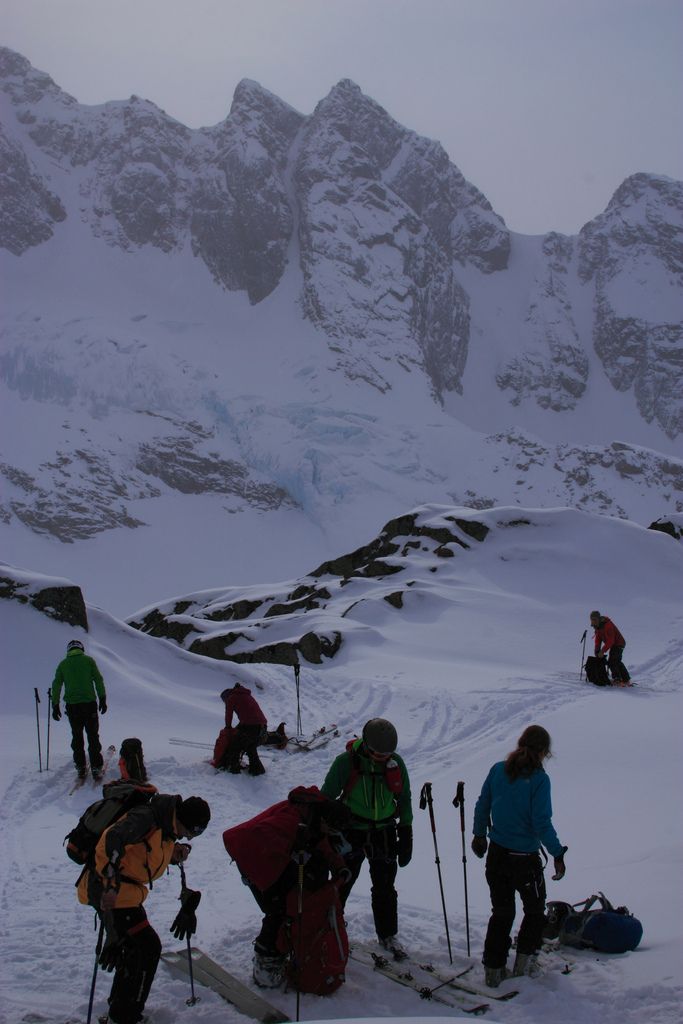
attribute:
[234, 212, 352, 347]
snow — white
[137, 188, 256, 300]
snow — white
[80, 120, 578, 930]
mountain — range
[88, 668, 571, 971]
people — grouped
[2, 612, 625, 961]
people — skiing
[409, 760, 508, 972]
poles — stuck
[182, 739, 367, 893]
snow — deep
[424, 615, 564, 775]
snow — white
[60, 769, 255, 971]
jacket — orange, black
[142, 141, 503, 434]
mountains — brown, white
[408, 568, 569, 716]
snow — white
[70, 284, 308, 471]
snow — white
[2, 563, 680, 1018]
snow — white